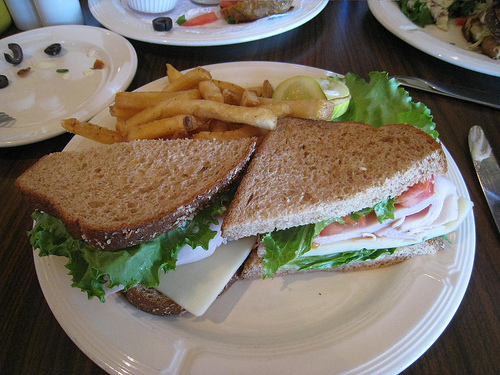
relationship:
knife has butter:
[468, 123, 499, 232] [468, 125, 488, 163]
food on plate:
[14, 63, 475, 318] [31, 61, 478, 374]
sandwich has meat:
[13, 117, 474, 317] [302, 175, 474, 256]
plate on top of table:
[31, 61, 478, 374] [1, 1, 499, 373]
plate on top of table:
[0, 24, 137, 149] [1, 1, 499, 373]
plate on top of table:
[87, 1, 327, 46] [1, 1, 499, 373]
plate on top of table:
[367, 2, 498, 77] [1, 1, 499, 373]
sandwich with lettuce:
[13, 117, 474, 317] [27, 70, 438, 302]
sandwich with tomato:
[13, 117, 474, 317] [321, 180, 435, 234]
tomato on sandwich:
[321, 180, 435, 234] [13, 117, 474, 317]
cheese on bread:
[154, 233, 257, 316] [122, 265, 243, 316]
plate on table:
[31, 61, 478, 374] [1, 1, 499, 373]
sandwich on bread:
[13, 117, 474, 317] [14, 136, 256, 253]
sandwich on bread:
[13, 117, 474, 317] [122, 265, 243, 316]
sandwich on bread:
[13, 117, 474, 317] [221, 115, 445, 243]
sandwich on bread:
[13, 117, 474, 317] [238, 226, 456, 280]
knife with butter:
[468, 123, 499, 232] [468, 125, 488, 163]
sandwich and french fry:
[13, 117, 474, 317] [60, 118, 127, 142]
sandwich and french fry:
[13, 117, 474, 317] [127, 115, 198, 141]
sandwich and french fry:
[13, 117, 474, 317] [162, 101, 278, 132]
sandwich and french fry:
[13, 117, 474, 317] [260, 97, 336, 122]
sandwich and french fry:
[13, 117, 474, 317] [163, 68, 212, 91]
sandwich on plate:
[13, 117, 474, 317] [31, 61, 478, 374]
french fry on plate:
[60, 118, 127, 142] [31, 61, 478, 374]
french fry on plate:
[127, 115, 198, 141] [31, 61, 478, 374]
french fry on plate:
[162, 101, 278, 132] [31, 61, 478, 374]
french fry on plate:
[260, 97, 336, 122] [31, 61, 478, 374]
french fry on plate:
[163, 68, 212, 91] [31, 61, 478, 374]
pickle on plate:
[273, 76, 351, 122] [31, 61, 478, 374]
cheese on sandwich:
[154, 233, 257, 316] [13, 117, 474, 317]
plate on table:
[0, 24, 137, 149] [1, 1, 499, 373]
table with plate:
[1, 1, 499, 373] [31, 61, 478, 374]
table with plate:
[1, 1, 499, 373] [0, 24, 137, 149]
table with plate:
[1, 1, 499, 373] [87, 1, 327, 46]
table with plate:
[1, 1, 499, 373] [367, 2, 498, 77]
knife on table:
[468, 123, 499, 232] [1, 1, 499, 373]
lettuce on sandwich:
[27, 70, 438, 302] [13, 117, 474, 317]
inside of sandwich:
[26, 175, 475, 317] [13, 117, 474, 317]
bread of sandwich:
[122, 265, 243, 316] [13, 117, 474, 317]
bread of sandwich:
[238, 226, 456, 280] [13, 117, 474, 317]